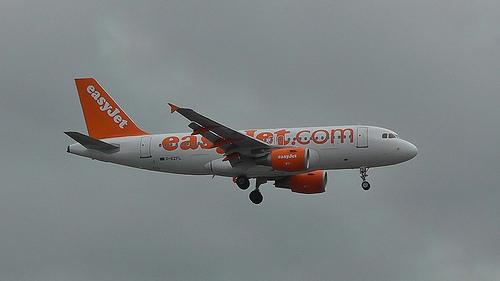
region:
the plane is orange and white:
[67, 76, 416, 203]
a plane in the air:
[65, 75, 418, 201]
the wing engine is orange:
[271, 146, 309, 170]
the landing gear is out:
[234, 167, 371, 204]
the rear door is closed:
[139, 136, 151, 158]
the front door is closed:
[358, 126, 368, 148]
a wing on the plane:
[166, 101, 266, 155]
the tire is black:
[361, 180, 371, 190]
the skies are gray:
[3, 3, 497, 277]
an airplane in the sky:
[61, 75, 417, 200]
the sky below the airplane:
[25, 195, 495, 270]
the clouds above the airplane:
[140, 5, 491, 96]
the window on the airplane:
[376, 130, 392, 140]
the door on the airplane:
[356, 127, 366, 143]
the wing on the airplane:
[170, 95, 306, 175]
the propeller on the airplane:
[292, 142, 312, 162]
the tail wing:
[70, 65, 140, 175]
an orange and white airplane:
[51, 63, 411, 195]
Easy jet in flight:
[41, 53, 471, 206]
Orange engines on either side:
[263, 148, 321, 169]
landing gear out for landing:
[351, 165, 375, 197]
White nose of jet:
[379, 124, 421, 164]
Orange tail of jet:
[74, 80, 138, 132]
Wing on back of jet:
[56, 126, 123, 157]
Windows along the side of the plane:
[294, 130, 358, 141]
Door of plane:
[355, 121, 372, 152]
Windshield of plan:
[383, 128, 400, 138]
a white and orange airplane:
[66, 66, 420, 202]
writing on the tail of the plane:
[85, 83, 136, 130]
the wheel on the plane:
[360, 178, 374, 194]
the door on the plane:
[359, 127, 371, 145]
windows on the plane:
[278, 135, 355, 145]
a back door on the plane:
[138, 137, 152, 153]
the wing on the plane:
[165, 106, 305, 178]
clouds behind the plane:
[13, 5, 493, 76]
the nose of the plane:
[383, 135, 425, 162]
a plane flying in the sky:
[28, 29, 475, 256]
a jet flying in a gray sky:
[13, 23, 483, 243]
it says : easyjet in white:
[89, 83, 129, 131]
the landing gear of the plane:
[230, 174, 372, 200]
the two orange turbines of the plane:
[269, 145, 325, 190]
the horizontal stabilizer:
[67, 126, 115, 154]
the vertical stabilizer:
[74, 77, 146, 137]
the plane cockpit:
[381, 131, 400, 139]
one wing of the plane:
[178, 106, 268, 161]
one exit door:
[140, 137, 149, 159]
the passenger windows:
[296, 134, 351, 141]